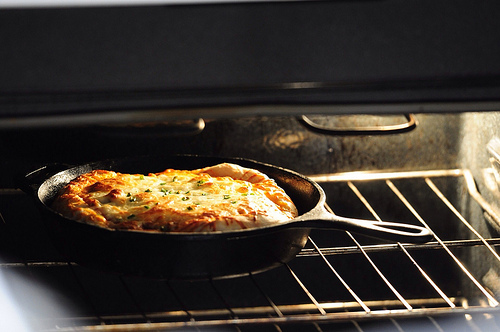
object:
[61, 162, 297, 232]
pizza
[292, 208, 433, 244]
handle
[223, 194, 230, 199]
green onion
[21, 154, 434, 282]
black pan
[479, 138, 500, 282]
grooves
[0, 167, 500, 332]
rack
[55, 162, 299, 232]
bread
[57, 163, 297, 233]
cheese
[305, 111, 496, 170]
oven light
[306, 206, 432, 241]
handle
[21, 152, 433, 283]
iron skillet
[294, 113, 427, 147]
broiler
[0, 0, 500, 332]
oven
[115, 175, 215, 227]
garnish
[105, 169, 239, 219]
spices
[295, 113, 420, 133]
element